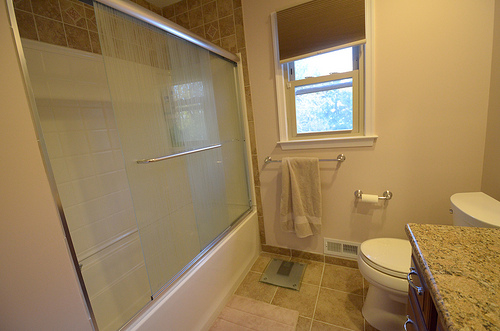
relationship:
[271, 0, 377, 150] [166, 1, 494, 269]
window on wall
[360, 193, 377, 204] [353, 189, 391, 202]
toilet paper on holder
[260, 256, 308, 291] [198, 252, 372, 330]
panel on floor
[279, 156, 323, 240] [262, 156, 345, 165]
towel on rack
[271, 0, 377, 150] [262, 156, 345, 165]
window above rack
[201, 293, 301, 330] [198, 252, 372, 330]
rug on floor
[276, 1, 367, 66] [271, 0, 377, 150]
blind on window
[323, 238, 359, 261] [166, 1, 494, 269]
vent on wall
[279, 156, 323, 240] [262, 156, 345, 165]
towel folded over rack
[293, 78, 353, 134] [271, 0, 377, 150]
pane on window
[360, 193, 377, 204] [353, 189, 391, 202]
toilet paper hanging from holder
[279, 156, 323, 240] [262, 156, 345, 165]
towel hanging on rack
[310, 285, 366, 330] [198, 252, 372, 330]
tile on floor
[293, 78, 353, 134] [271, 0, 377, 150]
tree outside window